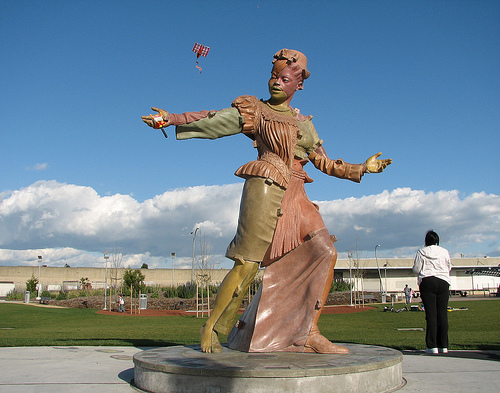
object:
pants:
[419, 276, 450, 348]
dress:
[169, 96, 362, 350]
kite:
[192, 43, 210, 75]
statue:
[141, 47, 392, 355]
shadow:
[54, 338, 185, 350]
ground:
[1, 343, 497, 392]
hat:
[271, 48, 310, 79]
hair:
[425, 230, 439, 245]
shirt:
[412, 246, 451, 285]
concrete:
[132, 342, 405, 392]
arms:
[172, 105, 365, 173]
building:
[0, 257, 500, 297]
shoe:
[426, 348, 438, 353]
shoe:
[439, 348, 449, 353]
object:
[150, 112, 168, 138]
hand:
[141, 106, 170, 129]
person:
[412, 231, 453, 355]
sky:
[0, 0, 500, 268]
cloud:
[0, 179, 500, 269]